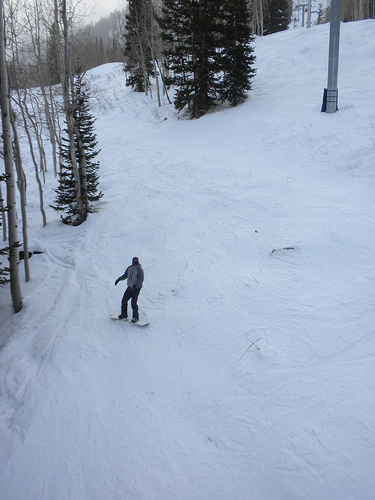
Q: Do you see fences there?
A: No, there are no fences.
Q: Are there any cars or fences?
A: No, there are no fences or cars.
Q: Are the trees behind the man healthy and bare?
A: Yes, the trees are healthy and bare.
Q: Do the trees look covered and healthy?
A: No, the trees are healthy but bare.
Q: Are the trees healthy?
A: Yes, the trees are healthy.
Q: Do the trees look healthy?
A: Yes, the trees are healthy.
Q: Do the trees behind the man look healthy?
A: Yes, the trees are healthy.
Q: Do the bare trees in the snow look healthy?
A: Yes, the trees are healthy.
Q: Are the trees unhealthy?
A: No, the trees are healthy.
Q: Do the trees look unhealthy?
A: No, the trees are healthy.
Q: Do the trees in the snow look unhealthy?
A: No, the trees are healthy.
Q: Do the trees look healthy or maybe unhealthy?
A: The trees are healthy.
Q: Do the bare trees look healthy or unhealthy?
A: The trees are healthy.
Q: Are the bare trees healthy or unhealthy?
A: The trees are healthy.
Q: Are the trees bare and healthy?
A: Yes, the trees are bare and healthy.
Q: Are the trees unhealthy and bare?
A: No, the trees are bare but healthy.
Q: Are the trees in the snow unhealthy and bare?
A: No, the trees are bare but healthy.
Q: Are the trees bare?
A: Yes, the trees are bare.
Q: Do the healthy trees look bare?
A: Yes, the trees are bare.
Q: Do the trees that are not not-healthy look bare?
A: Yes, the trees are bare.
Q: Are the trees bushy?
A: No, the trees are bare.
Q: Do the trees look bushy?
A: No, the trees are bare.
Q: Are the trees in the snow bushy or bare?
A: The trees are bare.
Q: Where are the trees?
A: The trees are in the snow.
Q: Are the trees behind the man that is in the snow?
A: Yes, the trees are behind the man.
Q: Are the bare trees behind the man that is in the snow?
A: Yes, the trees are behind the man.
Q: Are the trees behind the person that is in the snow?
A: Yes, the trees are behind the man.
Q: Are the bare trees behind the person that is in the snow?
A: Yes, the trees are behind the man.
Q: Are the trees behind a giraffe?
A: No, the trees are behind the man.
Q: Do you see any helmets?
A: No, there are no helmets.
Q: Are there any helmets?
A: No, there are no helmets.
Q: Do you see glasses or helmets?
A: No, there are no helmets or glasses.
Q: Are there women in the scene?
A: No, there are no women.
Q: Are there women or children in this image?
A: No, there are no women or children.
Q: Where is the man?
A: The man is in the snow.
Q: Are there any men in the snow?
A: Yes, there is a man in the snow.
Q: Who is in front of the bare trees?
A: The man is in front of the trees.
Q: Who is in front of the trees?
A: The man is in front of the trees.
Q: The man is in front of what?
A: The man is in front of the trees.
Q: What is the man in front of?
A: The man is in front of the trees.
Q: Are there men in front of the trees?
A: Yes, there is a man in front of the trees.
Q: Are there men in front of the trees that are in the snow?
A: Yes, there is a man in front of the trees.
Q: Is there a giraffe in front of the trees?
A: No, there is a man in front of the trees.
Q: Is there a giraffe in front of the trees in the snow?
A: No, there is a man in front of the trees.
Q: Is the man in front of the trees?
A: Yes, the man is in front of the trees.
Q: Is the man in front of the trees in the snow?
A: Yes, the man is in front of the trees.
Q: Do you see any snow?
A: Yes, there is snow.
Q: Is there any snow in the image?
A: Yes, there is snow.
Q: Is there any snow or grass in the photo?
A: Yes, there is snow.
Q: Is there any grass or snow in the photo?
A: Yes, there is snow.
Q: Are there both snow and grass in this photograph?
A: No, there is snow but no grass.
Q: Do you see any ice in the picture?
A: No, there is no ice.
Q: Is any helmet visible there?
A: No, there are no helmets.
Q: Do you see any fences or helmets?
A: No, there are no helmets or fences.